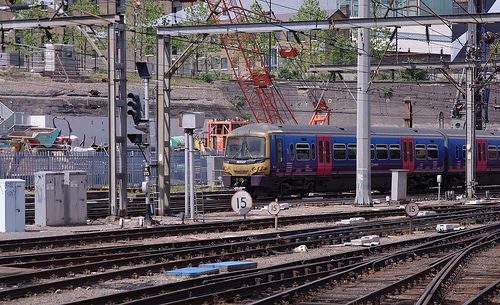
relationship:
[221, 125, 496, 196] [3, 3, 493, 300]
train at railroad station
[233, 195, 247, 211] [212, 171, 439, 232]
15 on signs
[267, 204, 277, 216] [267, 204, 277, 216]
15 on 15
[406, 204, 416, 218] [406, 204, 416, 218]
15 on 15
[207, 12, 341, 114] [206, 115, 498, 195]
red structure above train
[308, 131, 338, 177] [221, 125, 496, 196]
doors on a train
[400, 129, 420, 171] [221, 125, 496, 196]
doors on a train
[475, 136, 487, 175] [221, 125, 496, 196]
doors on a train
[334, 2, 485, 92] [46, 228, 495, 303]
building above train tracks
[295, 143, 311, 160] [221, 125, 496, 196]
window on a train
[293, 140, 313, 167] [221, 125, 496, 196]
window on a train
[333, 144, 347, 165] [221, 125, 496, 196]
window on a train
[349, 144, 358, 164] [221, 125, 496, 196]
window on a train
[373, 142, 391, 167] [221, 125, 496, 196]
window on a train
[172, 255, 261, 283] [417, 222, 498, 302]
panels on side of train tracks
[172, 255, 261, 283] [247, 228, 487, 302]
panels on side of train tracks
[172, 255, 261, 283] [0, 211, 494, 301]
panels on side of train tracks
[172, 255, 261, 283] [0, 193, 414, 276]
panels on side of train tracks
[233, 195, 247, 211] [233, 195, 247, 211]
15 on side of 15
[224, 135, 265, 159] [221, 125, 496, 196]
windshield on train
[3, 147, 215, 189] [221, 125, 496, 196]
fence beside train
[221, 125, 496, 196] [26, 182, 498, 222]
train going down track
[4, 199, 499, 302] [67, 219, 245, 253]
train track next to train track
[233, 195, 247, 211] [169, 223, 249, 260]
15 next to train track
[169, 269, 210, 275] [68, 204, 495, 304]
cover next to tracks